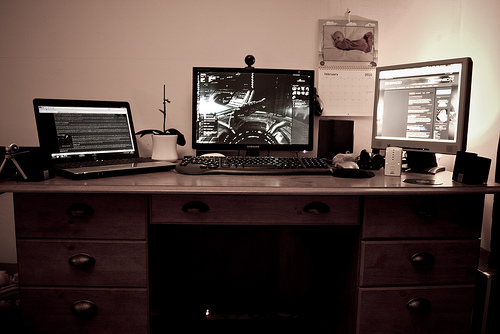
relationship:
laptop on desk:
[33, 97, 175, 183] [2, 156, 498, 333]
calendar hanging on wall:
[315, 16, 379, 120] [1, 1, 500, 264]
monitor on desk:
[191, 66, 315, 151] [2, 156, 498, 333]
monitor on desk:
[372, 57, 474, 157] [2, 156, 498, 333]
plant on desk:
[134, 84, 187, 147] [2, 156, 498, 333]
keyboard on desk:
[175, 155, 332, 177] [2, 156, 498, 333]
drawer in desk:
[13, 192, 149, 241] [2, 156, 498, 333]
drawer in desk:
[15, 239, 148, 287] [2, 156, 498, 333]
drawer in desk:
[149, 195, 365, 226] [2, 156, 498, 333]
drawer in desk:
[362, 195, 484, 239] [2, 156, 498, 333]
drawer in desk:
[359, 239, 480, 284] [2, 156, 498, 333]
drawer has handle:
[13, 192, 149, 241] [65, 202, 95, 221]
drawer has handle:
[15, 239, 148, 287] [67, 253, 96, 271]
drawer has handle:
[149, 195, 365, 226] [179, 199, 212, 215]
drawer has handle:
[362, 195, 484, 239] [414, 201, 442, 220]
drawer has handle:
[359, 239, 480, 284] [409, 250, 434, 268]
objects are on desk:
[1, 55, 492, 186] [2, 156, 498, 333]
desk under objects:
[2, 156, 498, 333] [1, 55, 492, 186]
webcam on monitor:
[244, 54, 256, 69] [191, 66, 315, 151]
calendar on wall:
[315, 16, 379, 120] [1, 1, 500, 264]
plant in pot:
[134, 84, 187, 147] [151, 134, 179, 162]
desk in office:
[2, 156, 498, 333] [1, 0, 500, 333]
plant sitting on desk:
[134, 84, 187, 147] [2, 156, 498, 333]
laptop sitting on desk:
[33, 97, 175, 183] [2, 156, 498, 333]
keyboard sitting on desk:
[175, 155, 332, 177] [2, 156, 498, 333]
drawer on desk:
[149, 195, 365, 226] [2, 156, 498, 333]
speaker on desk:
[20, 150, 56, 182] [2, 156, 498, 333]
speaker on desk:
[452, 151, 491, 187] [2, 156, 498, 333]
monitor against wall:
[191, 66, 315, 151] [1, 1, 500, 264]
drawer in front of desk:
[13, 192, 149, 241] [2, 156, 498, 333]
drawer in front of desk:
[149, 195, 365, 226] [2, 156, 498, 333]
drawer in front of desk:
[362, 195, 484, 239] [2, 156, 498, 333]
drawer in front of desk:
[359, 239, 480, 284] [2, 156, 498, 333]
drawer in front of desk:
[15, 239, 148, 287] [2, 156, 498, 333]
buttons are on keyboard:
[181, 158, 327, 170] [175, 155, 332, 177]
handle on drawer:
[65, 202, 95, 221] [13, 192, 149, 241]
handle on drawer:
[67, 253, 96, 271] [15, 239, 148, 287]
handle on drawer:
[179, 199, 212, 215] [149, 195, 365, 226]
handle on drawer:
[414, 201, 442, 220] [362, 195, 484, 239]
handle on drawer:
[409, 250, 434, 268] [359, 239, 480, 284]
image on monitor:
[197, 72, 310, 144] [191, 66, 315, 151]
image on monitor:
[378, 70, 459, 140] [372, 57, 474, 157]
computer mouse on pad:
[336, 160, 360, 169] [333, 168, 374, 177]